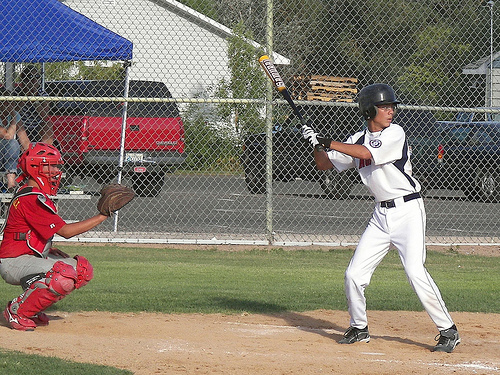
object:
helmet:
[14, 142, 64, 197]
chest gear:
[0, 191, 59, 247]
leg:
[401, 214, 460, 335]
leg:
[343, 227, 389, 329]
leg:
[3, 256, 80, 318]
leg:
[19, 248, 93, 313]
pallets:
[288, 74, 358, 104]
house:
[0, 0, 292, 149]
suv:
[41, 79, 187, 198]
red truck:
[46, 79, 189, 197]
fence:
[1, 0, 500, 243]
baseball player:
[298, 82, 462, 354]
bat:
[257, 53, 325, 153]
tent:
[0, 0, 135, 65]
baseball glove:
[96, 184, 137, 217]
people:
[0, 63, 54, 192]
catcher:
[0, 141, 138, 333]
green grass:
[0, 243, 499, 315]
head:
[368, 101, 396, 127]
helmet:
[358, 82, 402, 122]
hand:
[96, 183, 135, 216]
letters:
[259, 59, 285, 89]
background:
[0, 0, 265, 137]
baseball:
[0, 81, 463, 353]